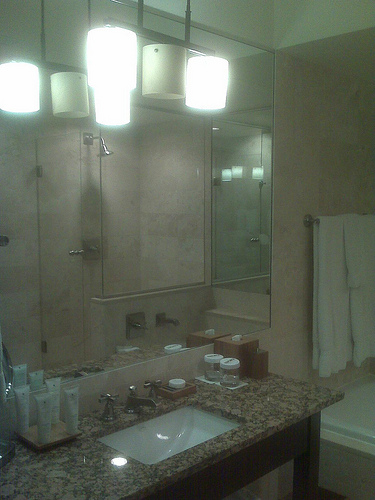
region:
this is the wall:
[276, 187, 295, 263]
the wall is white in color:
[282, 192, 291, 250]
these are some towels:
[319, 218, 370, 361]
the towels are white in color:
[319, 220, 368, 362]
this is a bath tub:
[351, 382, 372, 431]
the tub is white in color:
[349, 389, 374, 423]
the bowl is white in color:
[122, 429, 169, 446]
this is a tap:
[123, 381, 165, 412]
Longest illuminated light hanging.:
[87, 27, 139, 126]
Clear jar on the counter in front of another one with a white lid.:
[219, 356, 240, 387]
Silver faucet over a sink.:
[125, 385, 158, 415]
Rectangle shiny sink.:
[96, 398, 244, 468]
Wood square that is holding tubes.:
[16, 419, 82, 451]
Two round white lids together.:
[203, 353, 239, 371]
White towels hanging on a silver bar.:
[310, 214, 374, 375]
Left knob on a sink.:
[96, 391, 120, 421]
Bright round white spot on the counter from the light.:
[110, 455, 127, 467]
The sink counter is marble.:
[249, 386, 306, 415]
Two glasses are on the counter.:
[203, 352, 238, 385]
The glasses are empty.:
[202, 351, 237, 384]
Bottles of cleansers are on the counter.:
[15, 377, 79, 443]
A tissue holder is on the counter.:
[215, 331, 257, 351]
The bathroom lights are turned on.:
[84, 25, 229, 126]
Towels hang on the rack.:
[314, 216, 374, 377]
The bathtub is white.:
[350, 397, 370, 431]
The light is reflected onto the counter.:
[110, 455, 128, 467]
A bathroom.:
[6, 5, 371, 498]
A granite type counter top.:
[0, 362, 349, 498]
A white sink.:
[105, 396, 251, 466]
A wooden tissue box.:
[211, 329, 261, 384]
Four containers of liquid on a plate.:
[12, 367, 88, 456]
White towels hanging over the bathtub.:
[302, 197, 374, 377]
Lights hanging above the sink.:
[1, 13, 255, 162]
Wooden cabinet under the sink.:
[107, 408, 329, 497]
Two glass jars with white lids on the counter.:
[201, 351, 246, 391]